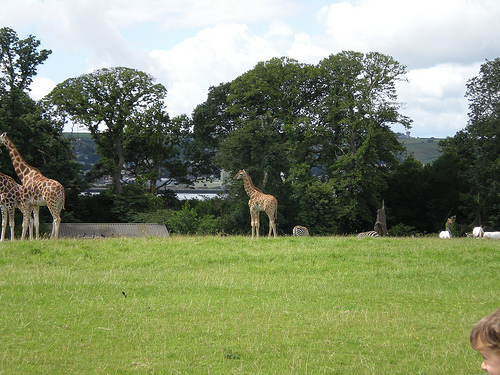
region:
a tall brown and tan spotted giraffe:
[0, 131, 62, 239]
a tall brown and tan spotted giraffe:
[1, 173, 35, 240]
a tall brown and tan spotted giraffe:
[234, 168, 279, 236]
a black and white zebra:
[291, 221, 311, 239]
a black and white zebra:
[356, 228, 381, 237]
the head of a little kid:
[465, 309, 498, 374]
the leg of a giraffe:
[18, 201, 30, 239]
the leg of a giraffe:
[30, 201, 42, 241]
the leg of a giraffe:
[49, 201, 61, 233]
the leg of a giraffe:
[248, 203, 258, 235]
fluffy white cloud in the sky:
[175, 33, 244, 68]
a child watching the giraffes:
[464, 314, 495, 374]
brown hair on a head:
[479, 316, 496, 336]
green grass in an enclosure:
[216, 270, 314, 327]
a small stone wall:
[88, 220, 171, 237]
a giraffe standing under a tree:
[225, 160, 287, 253]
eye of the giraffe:
[238, 171, 245, 177]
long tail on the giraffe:
[272, 202, 278, 222]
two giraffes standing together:
[5, 138, 77, 239]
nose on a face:
[478, 360, 487, 370]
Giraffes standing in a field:
[1, 126, 291, 254]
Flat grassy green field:
[6, 223, 467, 364]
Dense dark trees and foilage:
[187, 65, 397, 226]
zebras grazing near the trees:
[285, 218, 382, 245]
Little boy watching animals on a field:
[461, 293, 498, 373]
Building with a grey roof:
[30, 211, 182, 253]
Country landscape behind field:
[46, 123, 462, 198]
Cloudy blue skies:
[4, 2, 485, 143]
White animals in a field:
[434, 215, 498, 242]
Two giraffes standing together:
[0, 124, 78, 248]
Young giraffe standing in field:
[214, 165, 287, 242]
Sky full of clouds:
[65, 12, 217, 74]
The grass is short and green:
[165, 293, 301, 372]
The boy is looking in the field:
[454, 300, 496, 374]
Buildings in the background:
[74, 147, 218, 212]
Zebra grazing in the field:
[321, 222, 386, 237]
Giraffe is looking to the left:
[227, 161, 252, 184]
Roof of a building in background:
[67, 220, 196, 247]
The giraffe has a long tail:
[264, 197, 280, 217]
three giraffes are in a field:
[0, 120, 288, 251]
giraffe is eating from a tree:
[224, 160, 279, 240]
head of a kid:
[452, 300, 499, 374]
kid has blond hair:
[450, 300, 499, 372]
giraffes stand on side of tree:
[0, 133, 75, 247]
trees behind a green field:
[8, 35, 498, 235]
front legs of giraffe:
[241, 207, 261, 240]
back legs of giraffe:
[263, 211, 281, 243]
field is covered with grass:
[3, 230, 498, 373]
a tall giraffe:
[0, 131, 73, 241]